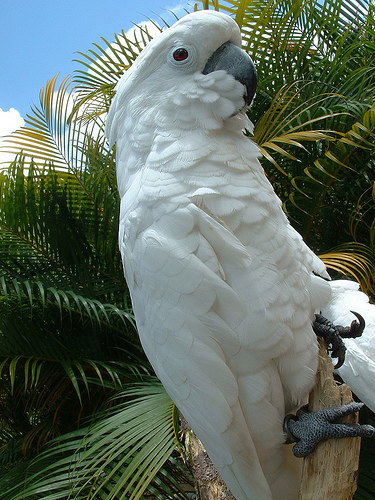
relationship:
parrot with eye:
[102, 4, 373, 489] [169, 45, 191, 66]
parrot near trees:
[102, 4, 373, 489] [4, 3, 373, 498]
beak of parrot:
[201, 39, 260, 106] [102, 4, 373, 489]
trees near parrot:
[4, 3, 373, 498] [102, 4, 373, 489]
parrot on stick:
[102, 4, 373, 489] [208, 324, 372, 482]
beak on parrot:
[201, 39, 260, 106] [102, 4, 373, 489]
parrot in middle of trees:
[102, 4, 373, 489] [4, 3, 373, 498]